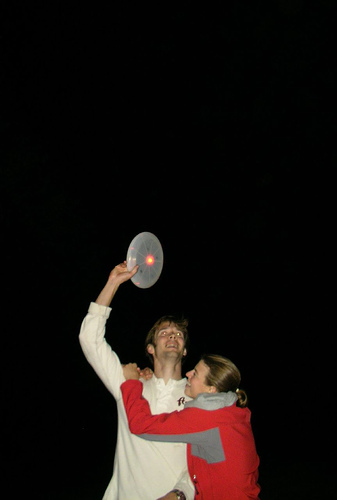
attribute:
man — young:
[74, 229, 212, 499]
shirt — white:
[79, 301, 200, 497]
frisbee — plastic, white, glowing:
[121, 232, 164, 288]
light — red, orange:
[143, 253, 154, 265]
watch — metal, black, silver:
[171, 486, 183, 500]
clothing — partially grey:
[119, 381, 259, 498]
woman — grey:
[172, 352, 261, 496]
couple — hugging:
[68, 240, 279, 475]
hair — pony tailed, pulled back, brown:
[201, 352, 246, 407]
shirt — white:
[107, 362, 190, 498]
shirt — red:
[116, 381, 270, 498]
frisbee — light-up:
[124, 230, 166, 291]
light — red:
[146, 255, 152, 264]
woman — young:
[120, 351, 261, 497]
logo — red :
[176, 395, 185, 408]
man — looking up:
[77, 257, 203, 498]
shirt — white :
[75, 298, 192, 498]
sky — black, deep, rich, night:
[1, 0, 336, 499]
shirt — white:
[81, 303, 190, 496]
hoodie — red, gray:
[119, 378, 262, 498]